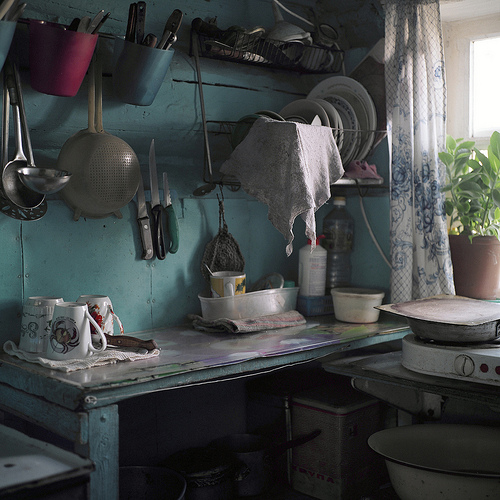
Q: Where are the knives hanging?
A: On the wall.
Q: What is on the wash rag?
A: Mugs.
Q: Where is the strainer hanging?
A: On the wall.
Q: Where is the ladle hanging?
A: On the wall.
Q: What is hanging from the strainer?
A: A wash rag.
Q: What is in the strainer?
A: Dishes.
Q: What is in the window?
A: A plant.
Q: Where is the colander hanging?
A: On the wall.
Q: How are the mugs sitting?
A: Upside down.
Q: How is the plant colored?
A: Green.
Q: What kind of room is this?
A: Kitchen.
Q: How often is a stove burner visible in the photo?
A: Once.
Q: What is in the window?
A: Potted plant.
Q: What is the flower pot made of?
A: Red clay.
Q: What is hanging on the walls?
A: Pots and cooking utensils.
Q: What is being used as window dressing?
A: Curtains.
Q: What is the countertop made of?
A: Wood.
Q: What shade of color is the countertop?
A: Green.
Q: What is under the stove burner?
A: White basin.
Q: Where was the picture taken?
A: Kitchen.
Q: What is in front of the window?
A: Plant.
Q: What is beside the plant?
A: Curtain.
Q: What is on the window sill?
A: A potted plant.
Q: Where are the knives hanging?
A: On the wall.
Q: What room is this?
A: The kitchen.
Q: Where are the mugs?
A: On the counter.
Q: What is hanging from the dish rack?
A: A dish towel.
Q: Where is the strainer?
A: On the wall.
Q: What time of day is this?
A: It's daytime.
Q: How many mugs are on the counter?
A: Four.